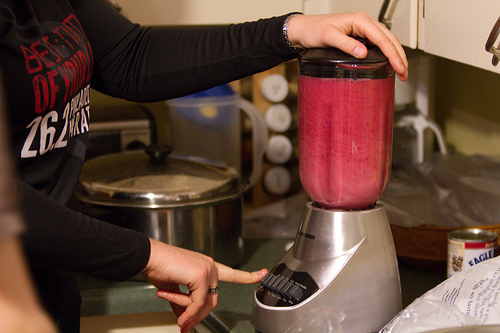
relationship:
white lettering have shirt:
[17, 112, 42, 165] [7, 15, 143, 256]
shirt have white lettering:
[7, 15, 143, 256] [17, 112, 42, 165]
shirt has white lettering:
[7, 15, 143, 256] [17, 112, 42, 165]